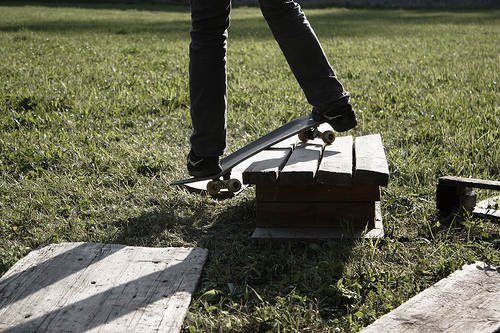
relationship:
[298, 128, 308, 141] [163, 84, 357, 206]
wheel on bottom of skateboard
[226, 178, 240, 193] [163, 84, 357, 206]
wheel on bottom of skateboard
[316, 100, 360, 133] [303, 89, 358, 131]
shoes on foot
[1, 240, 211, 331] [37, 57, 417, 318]
plywood lying on ground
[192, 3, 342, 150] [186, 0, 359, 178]
denim on boy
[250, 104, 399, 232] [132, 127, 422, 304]
plank on ground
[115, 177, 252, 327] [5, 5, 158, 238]
shadow on ground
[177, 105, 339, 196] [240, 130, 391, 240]
skateboard on table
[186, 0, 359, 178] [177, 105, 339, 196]
boy on skateboard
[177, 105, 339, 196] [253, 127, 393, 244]
skateboard on table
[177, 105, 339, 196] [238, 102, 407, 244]
skateboard on table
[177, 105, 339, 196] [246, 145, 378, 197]
skateboard on table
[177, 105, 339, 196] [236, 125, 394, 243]
skateboard on table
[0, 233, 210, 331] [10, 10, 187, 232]
wooden plank on yard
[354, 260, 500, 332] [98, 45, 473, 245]
plywood on yard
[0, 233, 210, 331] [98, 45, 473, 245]
wooden plank on yard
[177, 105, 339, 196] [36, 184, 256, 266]
skateboard tips toward ground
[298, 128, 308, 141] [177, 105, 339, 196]
wheel on a skateboard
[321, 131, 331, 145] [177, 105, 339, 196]
wheel on a skateboard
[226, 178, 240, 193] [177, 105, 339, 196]
wheel on a skateboard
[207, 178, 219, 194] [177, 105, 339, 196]
wheel on a skateboard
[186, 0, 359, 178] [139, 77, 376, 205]
boy on a skateboard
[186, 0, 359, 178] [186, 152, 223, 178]
boy wearing black shoes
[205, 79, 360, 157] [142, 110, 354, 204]
shoes on skateboard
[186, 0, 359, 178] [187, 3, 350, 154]
boy wearing denim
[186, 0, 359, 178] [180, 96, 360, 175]
boy wearing black shoes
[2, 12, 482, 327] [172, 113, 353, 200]
area near skateboard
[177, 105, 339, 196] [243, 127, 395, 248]
skateboard on top of wood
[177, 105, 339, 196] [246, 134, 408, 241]
skateboard on top of table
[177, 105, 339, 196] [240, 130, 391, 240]
skateboard on top of table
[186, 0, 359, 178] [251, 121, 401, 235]
boy standing atop table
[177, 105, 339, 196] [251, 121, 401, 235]
skateboard sitting atop table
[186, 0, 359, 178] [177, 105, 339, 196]
boy standing atop skateboard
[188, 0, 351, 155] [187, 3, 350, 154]
boy wearing denim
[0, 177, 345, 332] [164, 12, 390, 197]
shadow of person